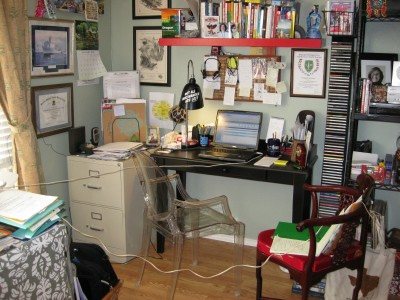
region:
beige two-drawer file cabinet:
[64, 144, 158, 264]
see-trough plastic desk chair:
[128, 147, 248, 298]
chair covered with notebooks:
[253, 171, 373, 299]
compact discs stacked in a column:
[316, 36, 354, 221]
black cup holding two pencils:
[265, 130, 282, 159]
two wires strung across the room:
[0, 159, 324, 281]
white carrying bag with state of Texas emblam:
[325, 211, 398, 299]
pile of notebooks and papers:
[85, 139, 148, 162]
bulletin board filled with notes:
[200, 52, 289, 106]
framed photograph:
[143, 124, 161, 146]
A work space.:
[0, 4, 396, 296]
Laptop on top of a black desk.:
[148, 108, 317, 252]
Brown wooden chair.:
[255, 172, 373, 297]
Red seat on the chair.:
[254, 218, 360, 270]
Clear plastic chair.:
[132, 146, 244, 295]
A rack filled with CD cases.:
[315, 30, 355, 216]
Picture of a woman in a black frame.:
[356, 52, 396, 112]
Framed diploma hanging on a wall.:
[30, 82, 76, 135]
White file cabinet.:
[66, 144, 151, 261]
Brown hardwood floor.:
[55, 235, 398, 299]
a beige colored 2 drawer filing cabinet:
[67, 146, 156, 263]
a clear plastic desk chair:
[129, 149, 245, 298]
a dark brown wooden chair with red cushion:
[255, 174, 375, 298]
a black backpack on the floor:
[71, 241, 119, 298]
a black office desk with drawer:
[152, 142, 318, 254]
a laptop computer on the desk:
[198, 108, 263, 164]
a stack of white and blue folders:
[0, 188, 66, 240]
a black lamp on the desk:
[179, 58, 204, 148]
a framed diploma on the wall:
[31, 82, 76, 137]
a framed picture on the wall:
[31, 23, 70, 68]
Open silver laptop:
[198, 107, 261, 162]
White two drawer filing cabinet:
[66, 140, 155, 262]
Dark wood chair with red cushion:
[255, 174, 376, 299]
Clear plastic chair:
[130, 147, 244, 299]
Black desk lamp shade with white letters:
[180, 76, 204, 112]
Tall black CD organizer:
[317, 32, 359, 218]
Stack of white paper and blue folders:
[0, 187, 67, 241]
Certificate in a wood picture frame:
[26, 82, 74, 138]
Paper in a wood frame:
[287, 45, 328, 98]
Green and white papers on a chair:
[268, 195, 365, 256]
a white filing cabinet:
[65, 144, 158, 265]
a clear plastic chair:
[126, 147, 246, 296]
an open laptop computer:
[196, 108, 261, 162]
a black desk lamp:
[176, 57, 202, 151]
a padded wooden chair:
[253, 168, 375, 297]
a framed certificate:
[30, 81, 74, 138]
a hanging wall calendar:
[73, 18, 107, 87]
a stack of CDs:
[317, 39, 354, 220]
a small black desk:
[150, 133, 316, 255]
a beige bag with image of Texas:
[322, 211, 396, 299]